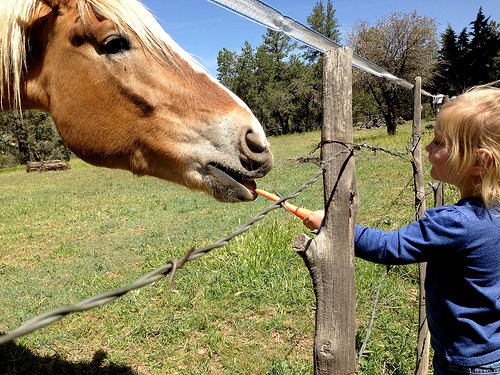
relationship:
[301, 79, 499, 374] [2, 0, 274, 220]
child feeding horse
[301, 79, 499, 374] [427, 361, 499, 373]
child wearing blue jeans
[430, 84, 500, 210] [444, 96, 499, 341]
hair belonging to girl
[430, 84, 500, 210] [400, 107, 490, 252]
hair belonging to girl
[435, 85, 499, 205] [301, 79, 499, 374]
hair belonging to child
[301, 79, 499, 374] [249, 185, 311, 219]
child holding carrot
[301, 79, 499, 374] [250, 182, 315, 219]
child holding carrot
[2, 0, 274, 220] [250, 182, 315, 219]
horse eating carrot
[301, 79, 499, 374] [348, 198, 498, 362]
child wearing shirt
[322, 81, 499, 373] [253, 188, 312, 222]
child holding out carrot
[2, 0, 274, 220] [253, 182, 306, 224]
horse taking carrot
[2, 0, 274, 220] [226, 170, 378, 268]
horse nibbling on carrot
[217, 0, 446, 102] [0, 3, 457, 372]
ribbon on fence